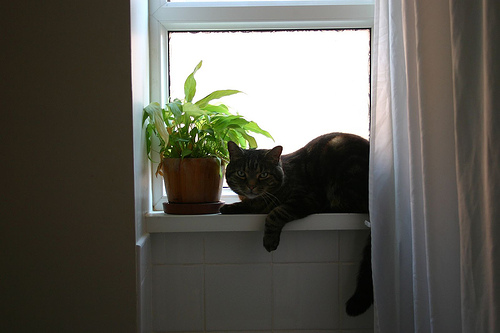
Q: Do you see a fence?
A: No, there are no fences.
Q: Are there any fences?
A: No, there are no fences.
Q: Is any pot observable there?
A: Yes, there is a pot.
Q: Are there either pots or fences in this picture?
A: Yes, there is a pot.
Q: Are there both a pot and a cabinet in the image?
A: No, there is a pot but no cabinets.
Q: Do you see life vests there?
A: No, there are no life vests.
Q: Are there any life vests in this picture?
A: No, there are no life vests.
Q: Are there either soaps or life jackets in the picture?
A: No, there are no life jackets or soaps.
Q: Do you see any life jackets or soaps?
A: No, there are no life jackets or soaps.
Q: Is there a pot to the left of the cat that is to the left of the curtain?
A: Yes, there is a pot to the left of the cat.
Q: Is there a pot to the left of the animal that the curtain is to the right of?
A: Yes, there is a pot to the left of the cat.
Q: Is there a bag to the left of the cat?
A: No, there is a pot to the left of the cat.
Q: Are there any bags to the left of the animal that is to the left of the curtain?
A: No, there is a pot to the left of the cat.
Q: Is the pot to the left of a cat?
A: Yes, the pot is to the left of a cat.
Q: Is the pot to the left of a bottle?
A: No, the pot is to the left of a cat.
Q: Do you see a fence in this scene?
A: No, there are no fences.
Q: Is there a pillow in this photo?
A: No, there are no pillows.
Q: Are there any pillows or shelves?
A: No, there are no pillows or shelves.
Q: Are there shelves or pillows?
A: No, there are no pillows or shelves.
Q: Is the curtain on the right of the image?
A: Yes, the curtain is on the right of the image.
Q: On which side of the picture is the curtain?
A: The curtain is on the right of the image.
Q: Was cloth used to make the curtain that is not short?
A: Yes, the curtain is made of cloth.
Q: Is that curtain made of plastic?
A: No, the curtain is made of cloth.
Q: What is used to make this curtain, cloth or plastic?
A: The curtain is made of cloth.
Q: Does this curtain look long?
A: Yes, the curtain is long.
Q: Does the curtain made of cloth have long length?
A: Yes, the curtain is long.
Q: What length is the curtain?
A: The curtain is long.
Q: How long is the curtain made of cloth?
A: The curtain is long.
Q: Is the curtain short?
A: No, the curtain is long.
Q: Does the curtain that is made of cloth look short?
A: No, the curtain is long.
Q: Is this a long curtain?
A: Yes, this is a long curtain.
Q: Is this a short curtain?
A: No, this is a long curtain.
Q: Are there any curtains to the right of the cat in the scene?
A: Yes, there is a curtain to the right of the cat.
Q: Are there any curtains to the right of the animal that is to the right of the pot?
A: Yes, there is a curtain to the right of the cat.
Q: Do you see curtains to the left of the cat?
A: No, the curtain is to the right of the cat.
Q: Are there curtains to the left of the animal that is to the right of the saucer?
A: No, the curtain is to the right of the cat.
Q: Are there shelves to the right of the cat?
A: No, there is a curtain to the right of the cat.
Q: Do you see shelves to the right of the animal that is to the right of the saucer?
A: No, there is a curtain to the right of the cat.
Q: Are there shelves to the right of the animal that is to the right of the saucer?
A: No, there is a curtain to the right of the cat.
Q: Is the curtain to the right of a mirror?
A: No, the curtain is to the right of the cat.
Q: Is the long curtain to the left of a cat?
A: No, the curtain is to the right of a cat.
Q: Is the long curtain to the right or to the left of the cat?
A: The curtain is to the right of the cat.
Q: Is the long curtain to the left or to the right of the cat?
A: The curtain is to the right of the cat.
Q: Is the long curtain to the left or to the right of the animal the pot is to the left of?
A: The curtain is to the right of the cat.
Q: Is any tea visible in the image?
A: No, there is no tea.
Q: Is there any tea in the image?
A: No, there is no tea.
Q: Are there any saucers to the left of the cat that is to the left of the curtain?
A: Yes, there is a saucer to the left of the cat.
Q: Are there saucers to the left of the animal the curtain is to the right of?
A: Yes, there is a saucer to the left of the cat.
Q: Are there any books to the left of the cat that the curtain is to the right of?
A: No, there is a saucer to the left of the cat.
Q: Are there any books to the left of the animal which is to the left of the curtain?
A: No, there is a saucer to the left of the cat.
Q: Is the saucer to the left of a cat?
A: Yes, the saucer is to the left of a cat.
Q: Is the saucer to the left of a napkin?
A: No, the saucer is to the left of a cat.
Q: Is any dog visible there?
A: No, there are no dogs.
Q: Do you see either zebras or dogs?
A: No, there are no dogs or zebras.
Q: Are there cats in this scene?
A: Yes, there is a cat.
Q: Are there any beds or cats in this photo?
A: Yes, there is a cat.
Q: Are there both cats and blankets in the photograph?
A: No, there is a cat but no blankets.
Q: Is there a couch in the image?
A: No, there are no couches.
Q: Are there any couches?
A: No, there are no couches.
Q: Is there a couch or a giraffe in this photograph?
A: No, there are no couches or giraffes.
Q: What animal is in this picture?
A: The animal is a cat.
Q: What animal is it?
A: The animal is a cat.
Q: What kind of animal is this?
A: That is a cat.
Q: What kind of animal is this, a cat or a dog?
A: That is a cat.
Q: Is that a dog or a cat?
A: That is a cat.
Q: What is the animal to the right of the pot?
A: The animal is a cat.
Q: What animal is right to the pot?
A: The animal is a cat.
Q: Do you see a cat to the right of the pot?
A: Yes, there is a cat to the right of the pot.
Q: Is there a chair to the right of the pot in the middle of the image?
A: No, there is a cat to the right of the pot.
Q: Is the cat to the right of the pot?
A: Yes, the cat is to the right of the pot.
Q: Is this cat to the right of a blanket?
A: No, the cat is to the right of the pot.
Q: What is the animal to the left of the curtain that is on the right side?
A: The animal is a cat.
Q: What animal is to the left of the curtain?
A: The animal is a cat.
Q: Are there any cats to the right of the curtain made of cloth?
A: No, the cat is to the left of the curtain.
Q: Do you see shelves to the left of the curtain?
A: No, there is a cat to the left of the curtain.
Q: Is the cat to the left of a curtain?
A: Yes, the cat is to the left of a curtain.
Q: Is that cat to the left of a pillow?
A: No, the cat is to the left of a curtain.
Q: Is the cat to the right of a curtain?
A: No, the cat is to the left of a curtain.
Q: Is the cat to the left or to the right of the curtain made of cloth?
A: The cat is to the left of the curtain.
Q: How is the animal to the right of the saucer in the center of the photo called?
A: The animal is a cat.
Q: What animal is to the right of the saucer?
A: The animal is a cat.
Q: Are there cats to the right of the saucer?
A: Yes, there is a cat to the right of the saucer.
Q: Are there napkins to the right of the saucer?
A: No, there is a cat to the right of the saucer.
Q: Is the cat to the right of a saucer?
A: Yes, the cat is to the right of a saucer.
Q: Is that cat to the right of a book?
A: No, the cat is to the right of a saucer.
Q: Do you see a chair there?
A: No, there are no chairs.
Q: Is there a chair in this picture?
A: No, there are no chairs.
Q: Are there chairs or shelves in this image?
A: No, there are no chairs or shelves.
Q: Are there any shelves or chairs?
A: No, there are no chairs or shelves.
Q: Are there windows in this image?
A: Yes, there is a window.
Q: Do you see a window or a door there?
A: Yes, there is a window.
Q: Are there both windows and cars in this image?
A: No, there is a window but no cars.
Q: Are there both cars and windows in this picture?
A: No, there is a window but no cars.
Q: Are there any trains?
A: No, there are no trains.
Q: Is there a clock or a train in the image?
A: No, there are no trains or clocks.